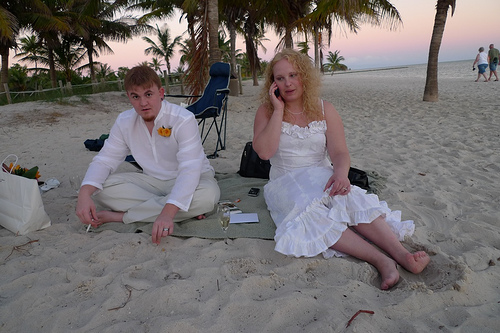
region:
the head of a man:
[122, 65, 169, 125]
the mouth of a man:
[136, 102, 153, 114]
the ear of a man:
[156, 84, 168, 101]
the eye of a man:
[142, 89, 155, 101]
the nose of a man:
[138, 93, 150, 107]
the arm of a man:
[74, 112, 127, 192]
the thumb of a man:
[87, 202, 101, 220]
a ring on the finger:
[161, 222, 171, 234]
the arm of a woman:
[242, 107, 289, 164]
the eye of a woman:
[272, 72, 285, 84]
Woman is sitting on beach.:
[237, 41, 442, 299]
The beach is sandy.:
[4, 68, 498, 330]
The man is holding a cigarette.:
[59, 65, 228, 249]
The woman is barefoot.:
[226, 38, 442, 311]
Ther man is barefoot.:
[53, 52, 225, 251]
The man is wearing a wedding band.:
[66, 54, 231, 256]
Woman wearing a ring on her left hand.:
[241, 43, 450, 295]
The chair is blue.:
[174, 50, 236, 169]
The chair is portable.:
[166, 45, 236, 185]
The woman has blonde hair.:
[234, 45, 448, 297]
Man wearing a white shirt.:
[83, 63, 218, 230]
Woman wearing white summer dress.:
[260, 52, 416, 254]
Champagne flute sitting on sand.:
[210, 201, 236, 248]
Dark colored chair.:
[180, 60, 234, 153]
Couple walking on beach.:
[466, 42, 498, 92]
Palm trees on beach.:
[2, 2, 392, 78]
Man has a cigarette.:
[80, 215, 102, 239]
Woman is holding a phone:
[260, 75, 294, 108]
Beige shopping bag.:
[0, 154, 55, 242]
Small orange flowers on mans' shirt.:
[154, 121, 180, 142]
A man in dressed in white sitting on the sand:
[77, 59, 227, 235]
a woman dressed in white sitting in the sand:
[247, 45, 434, 286]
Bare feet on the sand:
[359, 230, 441, 295]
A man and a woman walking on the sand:
[469, 37, 496, 83]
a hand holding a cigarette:
[70, 190, 107, 239]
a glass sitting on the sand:
[212, 195, 239, 252]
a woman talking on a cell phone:
[257, 45, 332, 112]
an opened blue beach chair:
[191, 55, 242, 155]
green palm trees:
[1, 9, 176, 62]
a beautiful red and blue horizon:
[354, 22, 427, 69]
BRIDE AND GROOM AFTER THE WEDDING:
[84, 62, 441, 294]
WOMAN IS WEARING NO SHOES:
[252, 49, 449, 299]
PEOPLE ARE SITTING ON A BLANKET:
[81, 133, 471, 285]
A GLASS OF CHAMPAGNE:
[203, 179, 250, 246]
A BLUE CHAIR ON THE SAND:
[159, 61, 285, 186]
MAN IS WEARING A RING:
[130, 220, 216, 241]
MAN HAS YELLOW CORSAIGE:
[63, 57, 215, 277]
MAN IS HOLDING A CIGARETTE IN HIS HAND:
[72, 67, 252, 283]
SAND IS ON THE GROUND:
[14, 22, 499, 328]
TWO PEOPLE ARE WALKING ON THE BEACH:
[469, 40, 499, 91]